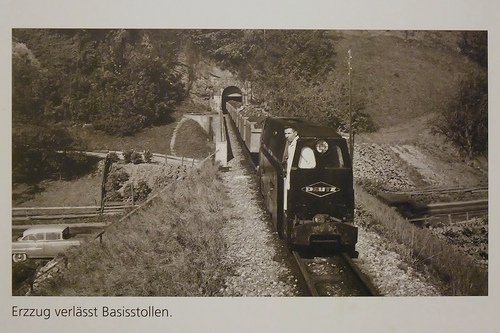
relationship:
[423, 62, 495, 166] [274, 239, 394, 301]
tree near tracks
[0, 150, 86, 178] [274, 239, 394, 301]
tree near tracks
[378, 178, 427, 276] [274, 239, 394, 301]
shrubs near tracks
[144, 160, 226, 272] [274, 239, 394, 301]
shrubs near tracks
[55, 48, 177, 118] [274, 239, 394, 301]
tree near tracks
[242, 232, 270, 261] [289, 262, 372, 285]
rocks around track